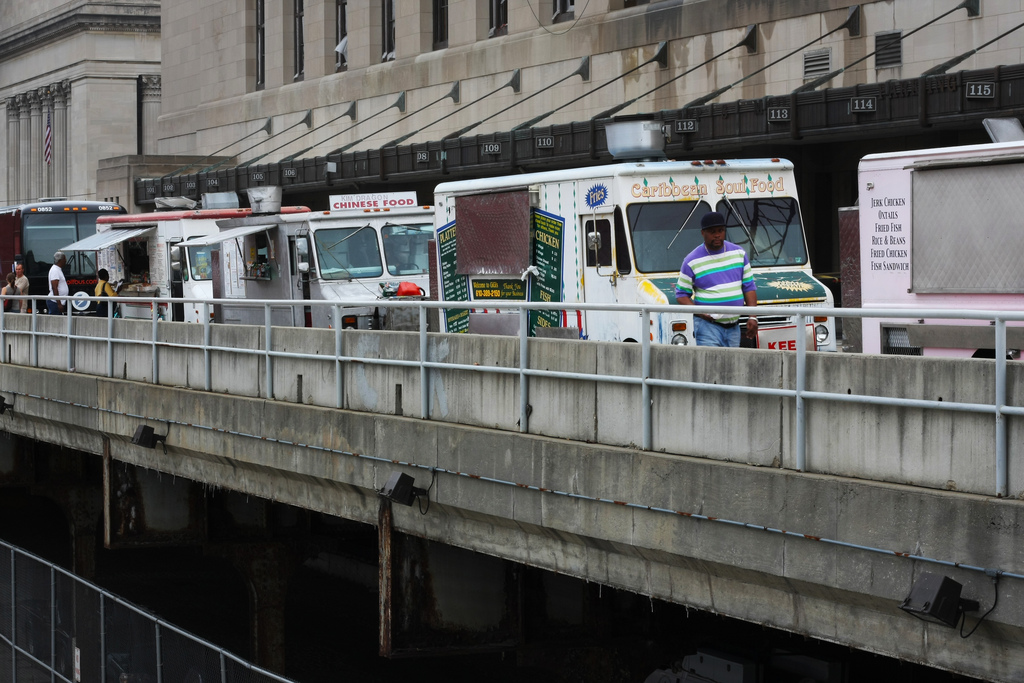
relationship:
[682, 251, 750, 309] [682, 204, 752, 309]
shirt worn by human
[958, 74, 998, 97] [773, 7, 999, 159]
number on building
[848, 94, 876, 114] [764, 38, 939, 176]
number on building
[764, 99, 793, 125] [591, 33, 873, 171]
number on building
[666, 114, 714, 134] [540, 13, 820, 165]
number on building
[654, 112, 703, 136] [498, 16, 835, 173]
number on building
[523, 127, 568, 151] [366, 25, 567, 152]
number on building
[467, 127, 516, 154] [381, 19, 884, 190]
number on building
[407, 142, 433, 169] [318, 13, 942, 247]
number on building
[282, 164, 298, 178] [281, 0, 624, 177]
number on building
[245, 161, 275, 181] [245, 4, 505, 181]
number on building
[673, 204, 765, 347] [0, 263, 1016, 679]
human walking down overpass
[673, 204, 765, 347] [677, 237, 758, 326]
human wearing shirt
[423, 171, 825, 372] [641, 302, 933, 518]
food truck parked on street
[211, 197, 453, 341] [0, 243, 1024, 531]
food truck parked on street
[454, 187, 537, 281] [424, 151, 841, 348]
window of food truck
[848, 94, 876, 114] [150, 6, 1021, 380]
number on wall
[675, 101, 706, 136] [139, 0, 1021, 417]
number on wall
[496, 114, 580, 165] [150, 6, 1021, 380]
number on wall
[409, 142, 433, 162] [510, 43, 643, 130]
number on wall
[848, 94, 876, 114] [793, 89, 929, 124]
number on wall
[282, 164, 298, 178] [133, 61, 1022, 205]
number on wall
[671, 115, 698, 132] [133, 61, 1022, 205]
number on wall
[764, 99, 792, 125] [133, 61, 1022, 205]
number on wall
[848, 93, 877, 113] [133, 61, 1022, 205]
number on wall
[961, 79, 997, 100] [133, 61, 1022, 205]
number on wall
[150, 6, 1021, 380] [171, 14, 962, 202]
wall of building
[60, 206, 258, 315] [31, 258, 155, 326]
food truck selling food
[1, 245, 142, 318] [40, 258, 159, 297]
people buying food